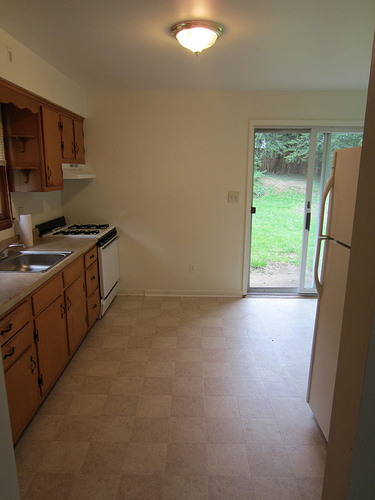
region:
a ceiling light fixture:
[163, 20, 227, 56]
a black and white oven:
[36, 215, 119, 317]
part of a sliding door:
[250, 119, 362, 292]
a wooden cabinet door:
[33, 295, 76, 386]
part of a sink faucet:
[1, 242, 30, 251]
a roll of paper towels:
[18, 210, 37, 249]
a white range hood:
[56, 163, 97, 179]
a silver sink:
[2, 248, 77, 273]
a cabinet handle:
[58, 300, 67, 317]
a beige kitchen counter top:
[26, 236, 101, 254]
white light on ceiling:
[165, 22, 214, 69]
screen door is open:
[246, 124, 321, 289]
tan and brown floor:
[75, 271, 270, 490]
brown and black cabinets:
[0, 247, 91, 427]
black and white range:
[45, 210, 123, 301]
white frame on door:
[242, 121, 307, 291]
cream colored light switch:
[225, 180, 233, 203]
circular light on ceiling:
[167, 15, 227, 55]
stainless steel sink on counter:
[6, 236, 54, 275]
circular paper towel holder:
[7, 212, 37, 235]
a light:
[139, 12, 300, 100]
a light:
[151, 18, 234, 55]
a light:
[157, 20, 243, 84]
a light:
[150, 14, 227, 64]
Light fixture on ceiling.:
[179, 27, 230, 68]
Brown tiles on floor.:
[112, 406, 221, 487]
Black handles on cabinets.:
[50, 288, 87, 329]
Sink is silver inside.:
[25, 252, 52, 288]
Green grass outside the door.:
[262, 241, 293, 274]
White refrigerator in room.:
[293, 306, 334, 402]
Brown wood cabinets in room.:
[20, 318, 84, 375]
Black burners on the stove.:
[70, 210, 91, 242]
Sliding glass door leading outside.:
[241, 248, 328, 298]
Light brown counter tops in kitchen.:
[8, 275, 32, 305]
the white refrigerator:
[302, 143, 370, 443]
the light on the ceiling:
[157, 14, 237, 59]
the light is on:
[167, 17, 230, 61]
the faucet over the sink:
[4, 241, 73, 276]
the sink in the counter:
[0, 241, 74, 283]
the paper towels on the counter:
[19, 207, 37, 247]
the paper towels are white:
[14, 212, 38, 248]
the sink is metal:
[3, 241, 78, 276]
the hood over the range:
[58, 160, 103, 180]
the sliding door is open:
[258, 125, 349, 291]